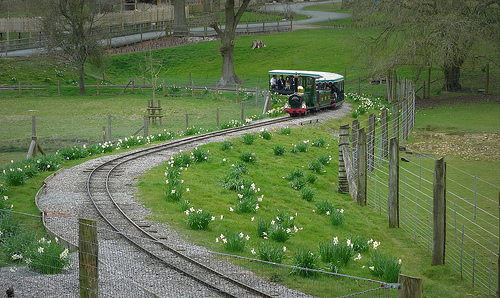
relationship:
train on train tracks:
[267, 69, 343, 116] [85, 116, 294, 297]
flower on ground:
[329, 232, 363, 266] [226, 227, 406, 277]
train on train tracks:
[267, 60, 349, 116] [80, 60, 316, 291]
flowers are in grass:
[0, 110, 405, 275] [0, 20, 495, 294]